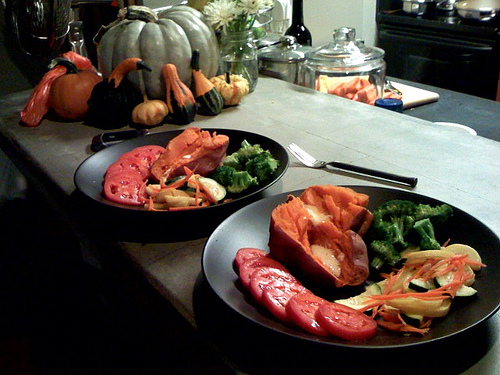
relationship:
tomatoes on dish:
[228, 245, 378, 340] [198, 180, 498, 360]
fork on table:
[287, 136, 428, 190] [4, 39, 499, 359]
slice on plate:
[316, 302, 378, 344] [199, 182, 498, 355]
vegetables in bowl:
[376, 248, 474, 309] [205, 188, 499, 353]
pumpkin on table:
[53, 69, 100, 111] [2, 80, 498, 372]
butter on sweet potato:
[308, 244, 340, 277] [268, 184, 371, 286]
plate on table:
[70, 125, 290, 222] [4, 39, 499, 359]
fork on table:
[293, 146, 414, 186] [218, 79, 495, 217]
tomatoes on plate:
[102, 140, 166, 205] [64, 120, 294, 219]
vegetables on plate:
[236, 185, 476, 336] [209, 179, 498, 374]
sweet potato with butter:
[268, 184, 371, 286] [310, 237, 342, 275]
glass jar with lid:
[295, 21, 390, 106] [291, 26, 388, 73]